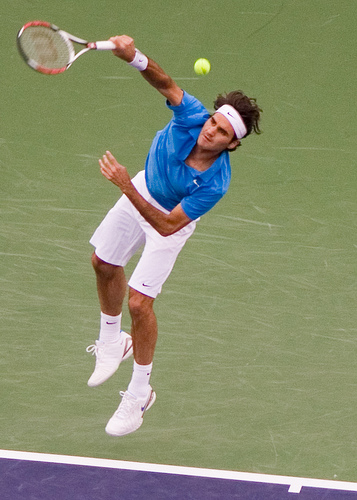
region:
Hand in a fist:
[117, 38, 131, 55]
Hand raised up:
[118, 38, 132, 55]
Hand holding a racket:
[115, 38, 132, 53]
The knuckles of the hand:
[120, 44, 129, 46]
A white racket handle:
[100, 43, 112, 47]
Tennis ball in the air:
[194, 60, 208, 73]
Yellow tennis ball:
[197, 61, 208, 72]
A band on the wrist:
[136, 55, 145, 67]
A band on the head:
[225, 109, 234, 116]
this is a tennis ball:
[155, 54, 217, 75]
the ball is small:
[190, 52, 212, 74]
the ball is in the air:
[190, 54, 209, 82]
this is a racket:
[11, 19, 122, 79]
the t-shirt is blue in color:
[154, 157, 179, 188]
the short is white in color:
[110, 223, 123, 241]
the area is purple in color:
[22, 459, 47, 493]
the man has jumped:
[15, 13, 258, 446]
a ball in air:
[189, 50, 221, 73]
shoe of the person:
[92, 378, 163, 436]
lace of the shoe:
[111, 382, 130, 407]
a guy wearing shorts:
[84, 205, 164, 299]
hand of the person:
[68, 137, 160, 215]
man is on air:
[67, 79, 238, 419]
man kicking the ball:
[49, 21, 276, 251]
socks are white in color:
[94, 314, 165, 380]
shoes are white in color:
[88, 349, 154, 431]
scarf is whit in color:
[220, 99, 250, 137]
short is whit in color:
[113, 185, 182, 276]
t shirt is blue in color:
[158, 124, 209, 204]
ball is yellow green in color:
[182, 35, 220, 84]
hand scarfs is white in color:
[119, 34, 155, 81]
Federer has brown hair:
[212, 90, 252, 134]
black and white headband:
[191, 86, 249, 143]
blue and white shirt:
[155, 112, 226, 218]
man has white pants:
[103, 177, 194, 302]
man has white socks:
[101, 312, 116, 340]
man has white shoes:
[105, 375, 150, 435]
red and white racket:
[3, 30, 72, 92]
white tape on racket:
[94, 26, 126, 68]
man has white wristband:
[122, 26, 139, 66]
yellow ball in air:
[185, 52, 213, 81]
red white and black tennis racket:
[15, 17, 139, 79]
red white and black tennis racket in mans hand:
[8, 19, 166, 84]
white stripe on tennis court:
[168, 465, 283, 483]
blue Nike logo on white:
[134, 388, 151, 419]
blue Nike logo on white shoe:
[96, 378, 163, 449]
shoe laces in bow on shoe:
[81, 338, 124, 384]